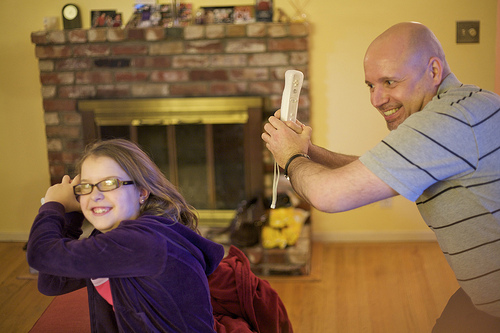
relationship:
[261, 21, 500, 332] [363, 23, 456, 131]
man has a head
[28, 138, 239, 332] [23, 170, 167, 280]
girl has arm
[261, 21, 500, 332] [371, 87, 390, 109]
man has nose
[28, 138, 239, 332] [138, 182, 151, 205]
girl has ear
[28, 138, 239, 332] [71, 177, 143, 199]
girl wearing eyeglasses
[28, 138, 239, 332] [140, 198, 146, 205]
girl wearing earrings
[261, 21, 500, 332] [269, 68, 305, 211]
man holding wii remote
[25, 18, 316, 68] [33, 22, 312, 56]
mantel made of bricks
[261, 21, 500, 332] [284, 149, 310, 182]
man wearing watch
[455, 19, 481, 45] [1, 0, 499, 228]
light switch attached to wall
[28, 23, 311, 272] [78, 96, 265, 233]
fireplace has gold trim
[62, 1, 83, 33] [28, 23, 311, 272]
clock on top of fireplace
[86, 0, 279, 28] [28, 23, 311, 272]
photos are on top of fireplace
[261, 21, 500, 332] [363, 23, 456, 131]
man has head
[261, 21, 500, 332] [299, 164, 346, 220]
man has elbow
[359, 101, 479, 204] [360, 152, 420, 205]
sleeve has edge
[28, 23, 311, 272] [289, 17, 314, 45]
fireplace has corner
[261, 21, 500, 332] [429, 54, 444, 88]
man has ear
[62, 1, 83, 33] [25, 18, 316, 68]
clock on top of mantle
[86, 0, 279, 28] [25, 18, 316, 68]
photos are on top of mantel